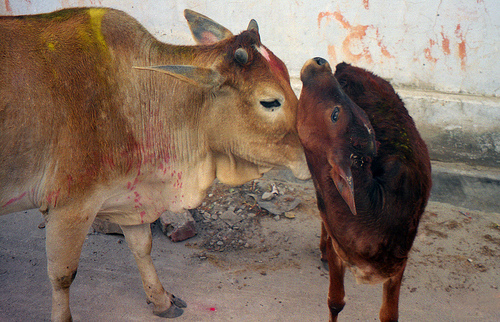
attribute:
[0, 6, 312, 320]
cow — light brown, brown, adult, large, light, tan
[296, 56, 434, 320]
calf — dark brown, browny, shorter, looking up, baby, smaller, small, dark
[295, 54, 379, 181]
head — up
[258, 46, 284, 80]
stain — red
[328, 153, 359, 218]
ear — big, pointy, long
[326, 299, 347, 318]
hoof — black, small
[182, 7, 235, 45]
ear — pointy, back, long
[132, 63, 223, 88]
ear — pointy, back, long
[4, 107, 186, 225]
stains — red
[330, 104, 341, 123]
eye — black, small, dark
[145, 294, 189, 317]
hoof — black, small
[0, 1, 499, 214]
wall — white, cement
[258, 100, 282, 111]
eye — black, small, dark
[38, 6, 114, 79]
paint — yellow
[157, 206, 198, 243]
brick — broken, red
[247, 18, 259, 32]
horn — stubby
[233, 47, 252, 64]
horn — stubby